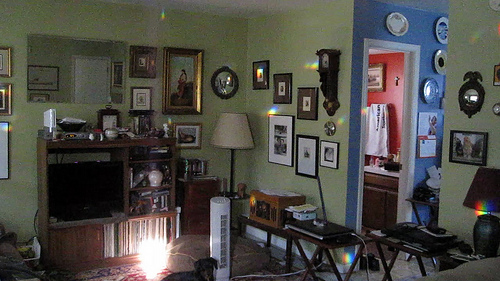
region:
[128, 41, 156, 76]
a picture on a wall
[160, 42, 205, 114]
a picture on a wall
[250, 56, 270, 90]
a picture on a wall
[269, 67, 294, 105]
a picture on a wall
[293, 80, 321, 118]
a picture on a wall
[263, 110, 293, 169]
a picture on a wall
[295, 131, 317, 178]
a picture on a wall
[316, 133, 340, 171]
a picture on a wall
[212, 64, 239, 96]
a mirror on a wall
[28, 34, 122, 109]
a mirror on a wall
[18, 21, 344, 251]
the walls are painted green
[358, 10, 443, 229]
this doorway goes to the bathroom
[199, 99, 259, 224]
the lampshade is tan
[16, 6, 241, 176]
there is a large mirror on the wall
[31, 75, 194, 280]
something is causing a lens flair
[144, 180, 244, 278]
black dog in front of air filter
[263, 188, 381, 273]
laptop on a tv stand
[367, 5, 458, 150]
there are hanging plates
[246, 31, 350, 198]
there are six pictures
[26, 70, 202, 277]
this is an entertainment center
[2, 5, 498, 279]
Living area in a house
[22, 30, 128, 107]
Glass mirror on the wall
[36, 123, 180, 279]
Entertainment center in the living room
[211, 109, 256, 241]
Lamp with white shade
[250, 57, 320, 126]
Three plaques on the wall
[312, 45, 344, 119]
Wooden clock on the wall in living room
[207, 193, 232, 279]
White portable fan in the living area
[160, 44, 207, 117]
Picture in a gold frame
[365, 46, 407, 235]
Entrance to the kitchen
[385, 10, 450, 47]
Souvenir plates on a blue wall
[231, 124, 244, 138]
part of a lamp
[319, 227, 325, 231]
a laptop on a table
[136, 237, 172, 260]
a bright bulb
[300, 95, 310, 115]
part of a wall painting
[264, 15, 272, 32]
part of a green wall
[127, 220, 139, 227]
part of a book shelf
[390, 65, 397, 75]
part of a red wall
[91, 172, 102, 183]
section of a t.v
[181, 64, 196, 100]
a painting on the wall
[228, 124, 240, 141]
upper part of a lamp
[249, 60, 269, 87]
a picture hanging on the wall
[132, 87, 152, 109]
a picture hanging on the wall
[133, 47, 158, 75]
a picture hanging on the wall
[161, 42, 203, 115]
a picture hanging on the wall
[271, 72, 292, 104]
a picture hanging on the wall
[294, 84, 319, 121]
a picture hanging on the wall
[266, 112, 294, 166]
a picture hanging on the wall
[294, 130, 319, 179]
a picture hanging on the wall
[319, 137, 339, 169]
a picture hanging on the wall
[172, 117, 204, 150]
a picture hanging on the wall